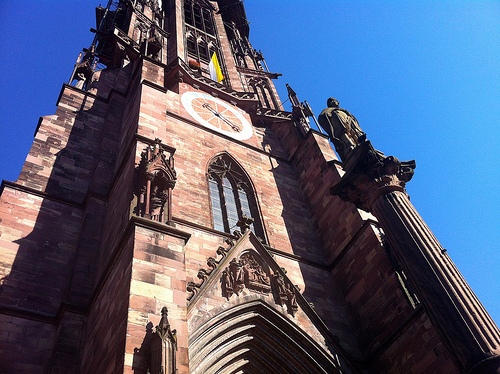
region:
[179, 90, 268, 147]
clock on the side of the tower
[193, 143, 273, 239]
window on the side of the tower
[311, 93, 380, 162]
statue of a person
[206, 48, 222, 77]
yellow and white flag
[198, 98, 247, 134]
two clock hands on the clock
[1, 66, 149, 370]
shadow on the building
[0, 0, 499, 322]
bright blue sky with no clouds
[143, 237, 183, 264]
black marks on the side of the building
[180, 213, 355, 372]
arch on the front of the building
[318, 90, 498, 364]
statue on top of the column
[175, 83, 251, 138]
the clock on the tower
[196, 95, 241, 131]
the hands of the clock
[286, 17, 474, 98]
the sky is blue and clear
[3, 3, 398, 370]
the tower is brick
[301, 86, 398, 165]
the statue on the column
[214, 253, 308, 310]
baas relief above the arches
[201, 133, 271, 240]
the window is arched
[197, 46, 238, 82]
the flag on the tower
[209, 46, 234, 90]
the flag is yellow and white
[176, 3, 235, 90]
large window above the clock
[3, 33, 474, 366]
this is a tall building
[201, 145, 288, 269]
this is a window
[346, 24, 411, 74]
the sky is clear and blue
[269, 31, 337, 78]
the sky is clear and blue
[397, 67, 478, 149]
the sky is clear and blue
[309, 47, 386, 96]
the sky is clear and blue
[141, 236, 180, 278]
these are blocks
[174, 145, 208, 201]
these are blocks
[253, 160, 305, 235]
these are blocks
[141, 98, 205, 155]
these are blocks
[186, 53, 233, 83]
flag on the building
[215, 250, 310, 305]
carvings of people on building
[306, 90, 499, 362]
column with man on top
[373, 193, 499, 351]
ridges on the column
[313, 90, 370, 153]
man on top of column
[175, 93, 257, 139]
clock on the building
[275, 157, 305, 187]
brick making up building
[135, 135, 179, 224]
house structure on buildng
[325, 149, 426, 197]
decorations on top of column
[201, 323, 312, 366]
ridges in a recess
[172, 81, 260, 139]
this is a clock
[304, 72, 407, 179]
this is a statue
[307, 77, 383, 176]
the statue is on a pillar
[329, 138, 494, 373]
this is a pillar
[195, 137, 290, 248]
this is a window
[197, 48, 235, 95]
a white and yellow flag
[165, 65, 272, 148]
the clock is red and white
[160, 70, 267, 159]
there is a star design in the middle of the clock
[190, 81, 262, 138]
these are the hands of the clock